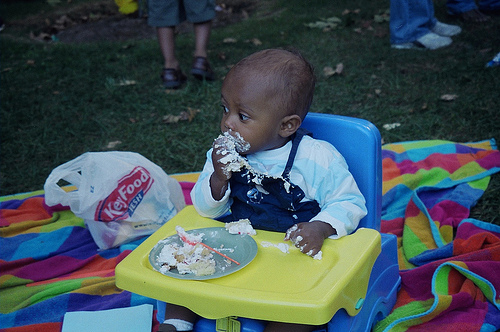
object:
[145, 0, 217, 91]
person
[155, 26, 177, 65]
leg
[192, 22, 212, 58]
leg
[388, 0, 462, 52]
person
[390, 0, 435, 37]
leg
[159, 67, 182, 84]
foot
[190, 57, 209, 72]
foot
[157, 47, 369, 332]
baby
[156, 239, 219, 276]
food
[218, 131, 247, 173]
food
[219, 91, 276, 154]
face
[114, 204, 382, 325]
tray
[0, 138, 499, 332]
beach blanket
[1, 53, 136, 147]
ground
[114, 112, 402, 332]
chair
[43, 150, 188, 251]
bag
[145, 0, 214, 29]
shorts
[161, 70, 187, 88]
shoe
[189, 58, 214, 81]
shoe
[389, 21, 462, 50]
tennis shoes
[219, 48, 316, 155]
head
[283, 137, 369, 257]
arm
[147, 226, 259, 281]
plate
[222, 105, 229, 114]
right eye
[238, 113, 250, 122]
left eye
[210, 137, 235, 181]
right hand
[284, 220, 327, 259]
left hand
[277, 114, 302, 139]
left ear